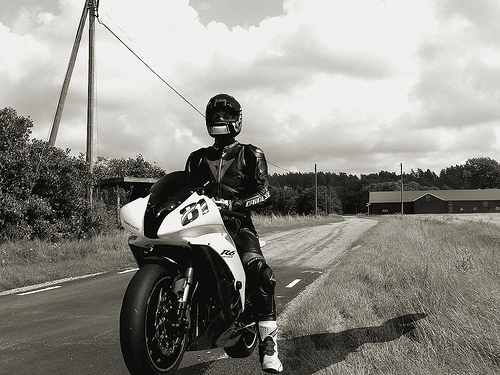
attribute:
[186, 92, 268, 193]
man — driving, riding, here, sitting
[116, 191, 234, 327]
bike — still, parked, here, close, white, black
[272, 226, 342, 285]
road — black, paved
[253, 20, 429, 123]
sky — close, bright, puffy, huge, big, cloudy, white, above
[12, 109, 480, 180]
tops — tree 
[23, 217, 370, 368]
road — paved 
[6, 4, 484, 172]
day — cloudy 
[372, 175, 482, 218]
building — long brown 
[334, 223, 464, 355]
grass — dry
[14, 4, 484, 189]
day — cloudy , sunny 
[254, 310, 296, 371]
boot — white